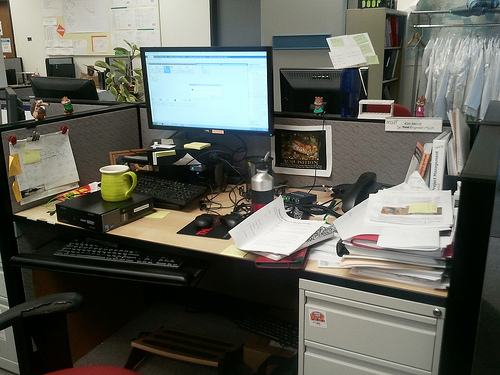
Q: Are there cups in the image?
A: Yes, there is a cup.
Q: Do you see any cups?
A: Yes, there is a cup.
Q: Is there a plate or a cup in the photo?
A: Yes, there is a cup.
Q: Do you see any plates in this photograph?
A: No, there are no plates.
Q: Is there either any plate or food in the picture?
A: No, there are no plates or food.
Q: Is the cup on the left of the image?
A: Yes, the cup is on the left of the image.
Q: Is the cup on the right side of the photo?
A: No, the cup is on the left of the image.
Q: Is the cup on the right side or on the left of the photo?
A: The cup is on the left of the image.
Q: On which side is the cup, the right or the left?
A: The cup is on the left of the image.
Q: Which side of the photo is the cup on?
A: The cup is on the left of the image.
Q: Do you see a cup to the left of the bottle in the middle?
A: Yes, there is a cup to the left of the bottle.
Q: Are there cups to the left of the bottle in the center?
A: Yes, there is a cup to the left of the bottle.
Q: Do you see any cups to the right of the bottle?
A: No, the cup is to the left of the bottle.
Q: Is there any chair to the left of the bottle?
A: No, there is a cup to the left of the bottle.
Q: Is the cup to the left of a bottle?
A: Yes, the cup is to the left of a bottle.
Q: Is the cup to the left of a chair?
A: No, the cup is to the left of a bottle.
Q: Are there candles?
A: No, there are no candles.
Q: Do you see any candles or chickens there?
A: No, there are no candles or chickens.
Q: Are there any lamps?
A: No, there are no lamps.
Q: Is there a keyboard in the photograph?
A: Yes, there is a keyboard.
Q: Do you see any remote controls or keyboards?
A: Yes, there is a keyboard.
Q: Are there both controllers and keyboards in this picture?
A: No, there is a keyboard but no controllers.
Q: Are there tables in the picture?
A: Yes, there is a table.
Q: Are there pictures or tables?
A: Yes, there is a table.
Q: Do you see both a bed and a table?
A: No, there is a table but no beds.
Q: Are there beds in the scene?
A: No, there are no beds.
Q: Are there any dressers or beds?
A: No, there are no beds or dressers.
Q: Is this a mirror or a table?
A: This is a table.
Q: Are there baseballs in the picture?
A: No, there are no baseballs.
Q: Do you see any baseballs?
A: No, there are no baseballs.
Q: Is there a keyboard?
A: Yes, there is a keyboard.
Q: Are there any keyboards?
A: Yes, there is a keyboard.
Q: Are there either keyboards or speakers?
A: Yes, there is a keyboard.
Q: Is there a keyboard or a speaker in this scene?
A: Yes, there is a keyboard.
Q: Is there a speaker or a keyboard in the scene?
A: Yes, there is a keyboard.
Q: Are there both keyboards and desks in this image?
A: Yes, there are both a keyboard and a desk.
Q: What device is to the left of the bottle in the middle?
A: The device is a keyboard.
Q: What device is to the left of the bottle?
A: The device is a keyboard.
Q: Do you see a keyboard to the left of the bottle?
A: Yes, there is a keyboard to the left of the bottle.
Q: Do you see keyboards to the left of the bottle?
A: Yes, there is a keyboard to the left of the bottle.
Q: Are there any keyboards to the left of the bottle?
A: Yes, there is a keyboard to the left of the bottle.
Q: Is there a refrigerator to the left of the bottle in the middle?
A: No, there is a keyboard to the left of the bottle.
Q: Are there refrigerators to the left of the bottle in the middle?
A: No, there is a keyboard to the left of the bottle.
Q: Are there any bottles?
A: Yes, there is a bottle.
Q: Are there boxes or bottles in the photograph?
A: Yes, there is a bottle.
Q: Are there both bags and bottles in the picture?
A: No, there is a bottle but no bags.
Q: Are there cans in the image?
A: No, there are no cans.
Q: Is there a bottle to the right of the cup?
A: Yes, there is a bottle to the right of the cup.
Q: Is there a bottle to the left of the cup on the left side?
A: No, the bottle is to the right of the cup.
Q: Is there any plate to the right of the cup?
A: No, there is a bottle to the right of the cup.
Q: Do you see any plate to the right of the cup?
A: No, there is a bottle to the right of the cup.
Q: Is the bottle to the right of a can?
A: No, the bottle is to the right of the cup.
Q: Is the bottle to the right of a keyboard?
A: Yes, the bottle is to the right of a keyboard.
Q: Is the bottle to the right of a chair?
A: No, the bottle is to the right of a keyboard.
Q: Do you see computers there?
A: Yes, there is a computer.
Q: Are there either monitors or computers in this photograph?
A: Yes, there is a computer.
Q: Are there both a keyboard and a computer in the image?
A: Yes, there are both a computer and a keyboard.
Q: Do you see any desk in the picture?
A: Yes, there is a desk.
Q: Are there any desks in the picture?
A: Yes, there is a desk.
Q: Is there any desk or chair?
A: Yes, there is a desk.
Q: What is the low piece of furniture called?
A: The piece of furniture is a desk.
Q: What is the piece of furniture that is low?
A: The piece of furniture is a desk.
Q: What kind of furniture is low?
A: The furniture is a desk.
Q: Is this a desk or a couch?
A: This is a desk.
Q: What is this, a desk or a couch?
A: This is a desk.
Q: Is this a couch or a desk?
A: This is a desk.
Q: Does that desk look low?
A: Yes, the desk is low.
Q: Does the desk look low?
A: Yes, the desk is low.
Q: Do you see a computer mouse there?
A: Yes, there is a computer mouse.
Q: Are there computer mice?
A: Yes, there is a computer mouse.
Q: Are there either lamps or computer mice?
A: Yes, there is a computer mouse.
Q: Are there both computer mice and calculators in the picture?
A: No, there is a computer mouse but no calculators.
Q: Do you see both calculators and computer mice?
A: No, there is a computer mouse but no calculators.